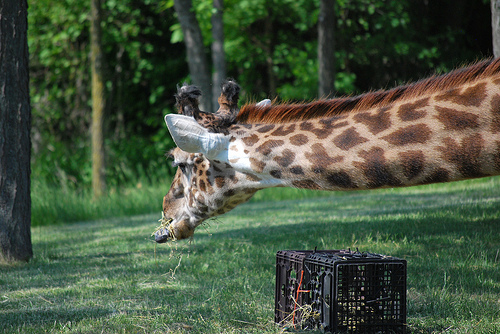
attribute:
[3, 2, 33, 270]
trunk — tree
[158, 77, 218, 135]
ear — giraffe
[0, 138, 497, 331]
field — green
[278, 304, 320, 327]
straw — inside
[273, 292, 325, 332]
straw — sticking out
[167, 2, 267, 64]
leaves — green, tree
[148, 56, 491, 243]
giraffe — spotted, eating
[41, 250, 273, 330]
grass — green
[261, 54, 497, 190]
neck — giraffe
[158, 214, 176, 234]
mouth — giraffe